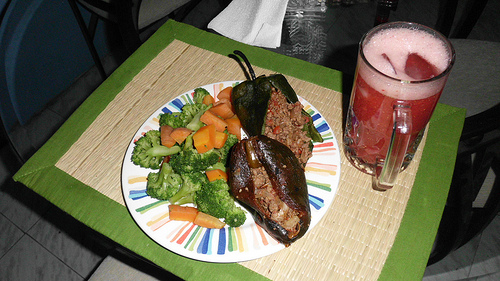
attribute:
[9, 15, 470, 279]
place mat — green, brown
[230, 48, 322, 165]
pepper — green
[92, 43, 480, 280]
mat — tan, green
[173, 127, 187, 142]
carrot — cut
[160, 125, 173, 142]
carrot — cut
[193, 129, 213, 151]
carrot — cut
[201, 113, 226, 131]
carrot — cut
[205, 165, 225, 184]
carrot — cut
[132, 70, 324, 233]
supper — healthy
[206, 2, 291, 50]
towel — white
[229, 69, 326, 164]
pepper — green, stuffed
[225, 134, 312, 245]
pepper — green, stuffed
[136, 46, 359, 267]
white plate — round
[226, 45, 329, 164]
stuffed pepper — roasted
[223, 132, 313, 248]
stuffed pepper — roasted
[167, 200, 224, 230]
carrot — cooked, sliced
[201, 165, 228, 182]
carrot — cooked, sliced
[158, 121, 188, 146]
carrot — cooked, sliced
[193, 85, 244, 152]
carrot — cooked, sliced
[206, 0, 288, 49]
napkin — white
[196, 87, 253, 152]
carrots — sliced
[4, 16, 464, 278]
placemat — wicker, cotton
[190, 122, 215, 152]
carrot — cooked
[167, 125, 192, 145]
carrot — cooked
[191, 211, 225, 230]
carrot — cooked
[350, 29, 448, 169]
drink — pink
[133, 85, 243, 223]
broccoli — steamed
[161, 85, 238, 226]
carrots — steamed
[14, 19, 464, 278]
border — green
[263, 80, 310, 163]
rice — brown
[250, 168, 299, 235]
rice — brown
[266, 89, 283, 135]
tomato — flecks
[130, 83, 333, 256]
stripes — orange, blue, green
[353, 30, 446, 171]
pop — red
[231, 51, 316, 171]
pepper — stuffed, green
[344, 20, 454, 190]
mug — clear, glass